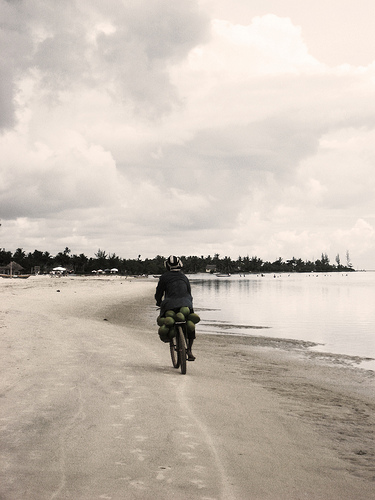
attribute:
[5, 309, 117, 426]
sand — grey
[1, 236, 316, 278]
trees — in distance, dark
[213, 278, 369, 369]
water — calm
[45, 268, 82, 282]
house — in distance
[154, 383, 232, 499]
track — thin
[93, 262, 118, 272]
umbrella — white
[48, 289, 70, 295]
object — small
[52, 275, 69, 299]
spot — black